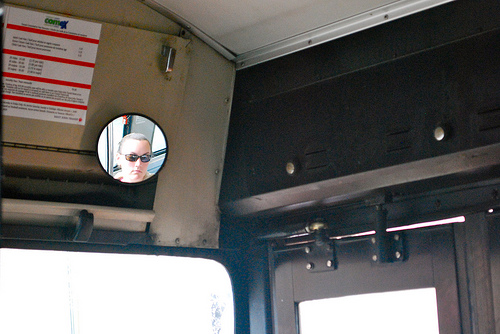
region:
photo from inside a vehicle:
[18, 10, 479, 325]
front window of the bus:
[0, 240, 241, 330]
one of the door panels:
[261, 225, 453, 330]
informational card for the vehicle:
[0, 0, 95, 125]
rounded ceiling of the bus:
[161, 0, 446, 65]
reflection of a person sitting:
[95, 110, 166, 180]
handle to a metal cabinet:
[147, 36, 178, 76]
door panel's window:
[290, 282, 445, 327]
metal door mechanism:
[257, 202, 479, 263]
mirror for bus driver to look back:
[97, 110, 163, 182]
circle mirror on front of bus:
[91, 113, 172, 181]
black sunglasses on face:
[113, 150, 158, 169]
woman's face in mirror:
[88, 113, 171, 186]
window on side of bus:
[103, 115, 124, 162]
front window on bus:
[13, 246, 239, 331]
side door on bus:
[267, 216, 472, 331]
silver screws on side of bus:
[429, 127, 446, 144]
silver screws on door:
[389, 245, 410, 264]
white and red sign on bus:
[0, 8, 122, 128]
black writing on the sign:
[10, 33, 60, 60]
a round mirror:
[70, 72, 182, 199]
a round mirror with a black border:
[79, 90, 199, 195]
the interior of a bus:
[3, 3, 498, 328]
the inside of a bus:
[0, 3, 497, 331]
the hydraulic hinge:
[245, 175, 495, 260]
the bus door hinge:
[240, 150, 497, 257]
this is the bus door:
[264, 197, 493, 332]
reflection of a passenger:
[98, 115, 170, 183]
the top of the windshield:
[7, 238, 243, 333]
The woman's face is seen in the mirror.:
[97, 118, 184, 184]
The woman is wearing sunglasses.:
[123, 142, 155, 167]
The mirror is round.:
[89, 108, 184, 183]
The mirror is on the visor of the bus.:
[5, 5, 180, 207]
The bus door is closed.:
[266, 210, 480, 331]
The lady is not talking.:
[110, 130, 169, 185]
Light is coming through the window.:
[0, 248, 162, 333]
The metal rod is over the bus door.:
[264, 200, 494, 274]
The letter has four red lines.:
[0, 19, 102, 126]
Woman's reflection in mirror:
[118, 129, 153, 181]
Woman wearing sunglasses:
[123, 151, 155, 163]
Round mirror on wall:
[95, 112, 170, 187]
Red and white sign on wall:
[2, 6, 101, 130]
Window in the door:
[290, 286, 442, 331]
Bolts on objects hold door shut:
[301, 207, 408, 272]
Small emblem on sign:
[37, 16, 71, 31]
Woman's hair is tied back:
[116, 132, 158, 152]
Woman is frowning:
[126, 166, 148, 179]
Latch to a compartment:
[157, 39, 179, 84]